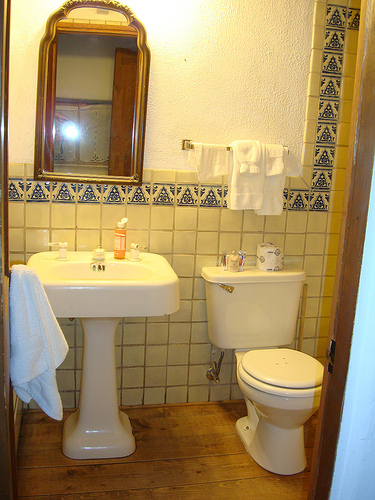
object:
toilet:
[200, 257, 326, 477]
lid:
[237, 347, 324, 402]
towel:
[226, 140, 265, 217]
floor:
[19, 395, 315, 498]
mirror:
[32, 0, 152, 186]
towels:
[226, 137, 301, 219]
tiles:
[307, 1, 358, 215]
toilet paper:
[253, 241, 289, 273]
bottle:
[112, 218, 128, 258]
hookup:
[204, 349, 228, 385]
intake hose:
[214, 349, 227, 371]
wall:
[8, 8, 314, 407]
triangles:
[322, 26, 346, 51]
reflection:
[57, 115, 85, 140]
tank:
[198, 263, 306, 349]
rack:
[182, 136, 303, 155]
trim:
[130, 33, 151, 182]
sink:
[25, 247, 181, 319]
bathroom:
[3, 0, 362, 498]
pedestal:
[61, 316, 136, 459]